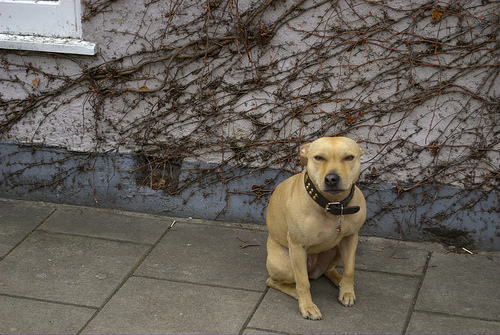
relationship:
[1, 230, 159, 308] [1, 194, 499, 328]
cement tile on sidewalk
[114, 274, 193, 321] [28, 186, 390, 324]
cement tile on sidewalk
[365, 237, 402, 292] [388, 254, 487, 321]
tile on sidewalk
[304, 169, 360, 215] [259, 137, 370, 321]
collar on dog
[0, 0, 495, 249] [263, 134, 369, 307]
wall behind dog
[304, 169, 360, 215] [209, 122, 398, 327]
collar on dog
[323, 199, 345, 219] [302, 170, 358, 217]
buckle of collar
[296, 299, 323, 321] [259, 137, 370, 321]
paw of dog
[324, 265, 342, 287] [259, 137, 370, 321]
paw of dog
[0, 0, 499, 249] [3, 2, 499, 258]
wall on side of building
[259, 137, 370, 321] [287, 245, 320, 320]
dog has right leg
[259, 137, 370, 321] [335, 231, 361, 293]
dog has left leg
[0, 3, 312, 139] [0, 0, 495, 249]
branch on wall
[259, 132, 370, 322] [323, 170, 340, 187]
dog has nose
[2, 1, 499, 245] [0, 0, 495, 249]
vines growing on wall